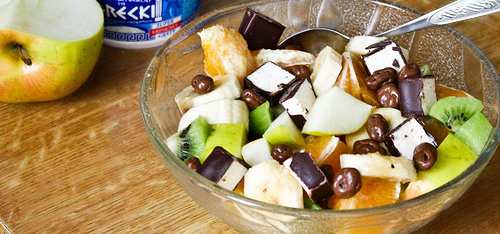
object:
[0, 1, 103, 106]
apple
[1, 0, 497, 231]
table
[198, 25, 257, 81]
piece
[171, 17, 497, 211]
salad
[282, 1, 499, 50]
spoon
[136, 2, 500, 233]
bowl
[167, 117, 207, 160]
piece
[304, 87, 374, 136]
slice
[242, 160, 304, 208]
piece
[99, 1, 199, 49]
container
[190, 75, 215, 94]
raisin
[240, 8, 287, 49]
chocolate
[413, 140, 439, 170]
chocolate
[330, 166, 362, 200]
chocolate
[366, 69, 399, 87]
chocolate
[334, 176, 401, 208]
slice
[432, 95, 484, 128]
kiwi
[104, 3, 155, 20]
lettering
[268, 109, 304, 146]
wedge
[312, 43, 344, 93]
banana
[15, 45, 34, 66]
stem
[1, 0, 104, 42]
flesh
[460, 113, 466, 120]
seed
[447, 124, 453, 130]
seed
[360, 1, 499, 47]
handle